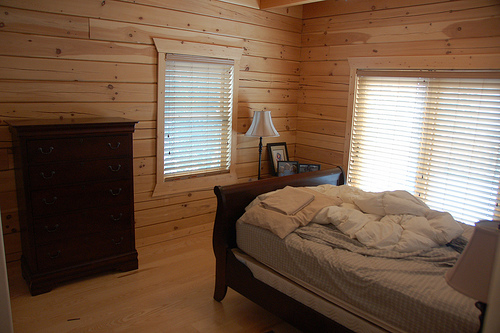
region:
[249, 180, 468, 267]
Pile of bed sheets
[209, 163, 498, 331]
messy unmade bed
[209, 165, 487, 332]
Brown slay bed with white sheets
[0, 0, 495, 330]
Bedroom with bare wood walls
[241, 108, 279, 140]
White table lamp shade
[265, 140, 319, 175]
Pictures in black picture frames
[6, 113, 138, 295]
Dark brown dresser with five drawers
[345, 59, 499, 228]
Wood framed window with white blinds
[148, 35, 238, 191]
White horizontal blinds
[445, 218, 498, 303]
White lampshade near the bed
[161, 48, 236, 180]
Blinds covering a window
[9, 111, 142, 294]
A brown wooden dresser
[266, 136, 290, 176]
A rectangle shaped photo frame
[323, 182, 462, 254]
White comforter on the bed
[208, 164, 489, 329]
A bed in a bedroom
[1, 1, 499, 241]
Wood paneling on the walls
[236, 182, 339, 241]
Beige pillow on the bed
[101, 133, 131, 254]
Handles on the drawers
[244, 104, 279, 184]
A white lamp shade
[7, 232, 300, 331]
A brown wooden floor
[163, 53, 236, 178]
white blinds on a window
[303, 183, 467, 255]
a crumpled white duvet on a bed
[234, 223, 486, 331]
white and blue stripe sheets on a bed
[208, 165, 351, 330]
wooden frame of a bed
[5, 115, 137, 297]
a wooden dresser in a bedroom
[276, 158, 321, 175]
framed picture on a night table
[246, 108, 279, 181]
a white lamp on a night table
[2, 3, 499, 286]
wooden walls in a bedroom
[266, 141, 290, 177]
a framed picture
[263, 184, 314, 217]
a folded pillow case on a bed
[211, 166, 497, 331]
an unmade bed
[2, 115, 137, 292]
a brown bureau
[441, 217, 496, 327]
the lamp by the bed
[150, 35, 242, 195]
the window with a white shade next to a lamp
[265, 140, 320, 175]
group of framed pictures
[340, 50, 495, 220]
framed window with blinds by the bed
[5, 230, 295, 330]
the wood floor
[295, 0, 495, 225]
wood paneled wall by the bed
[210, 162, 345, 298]
the bed's footboard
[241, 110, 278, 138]
the white lamp shade by the pictures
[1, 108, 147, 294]
brown dresser in bedroom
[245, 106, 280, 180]
lamp on the stand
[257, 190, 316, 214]
towel on the bed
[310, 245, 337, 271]
striped sheets on the bed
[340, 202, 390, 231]
white blanket on the bed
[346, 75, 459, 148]
white blinds on the window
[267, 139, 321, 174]
pictures on the stand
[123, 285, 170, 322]
tan wooden hardwood floor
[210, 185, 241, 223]
footboard on the bed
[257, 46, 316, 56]
tan wooden wall